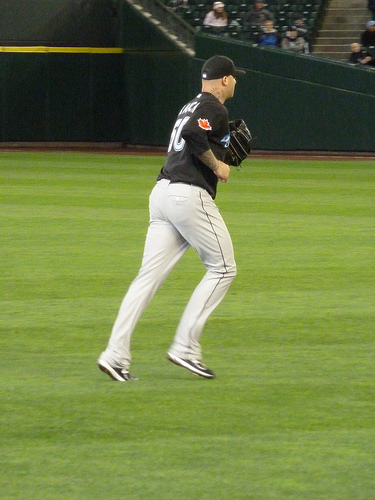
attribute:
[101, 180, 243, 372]
pants — white, bunched up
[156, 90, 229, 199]
t shirt — black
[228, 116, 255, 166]
glove — black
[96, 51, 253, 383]
man — playing baseball, jogging, running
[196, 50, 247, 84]
hat — black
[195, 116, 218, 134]
tag — red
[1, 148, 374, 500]
grass — green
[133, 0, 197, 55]
stairs — leading down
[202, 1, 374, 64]
people — watching the game, enjoying the game, dressed warmly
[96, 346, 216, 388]
cleats — black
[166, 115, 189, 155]
numbers — white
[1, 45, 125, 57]
line — yellow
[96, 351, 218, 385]
feet — in motion